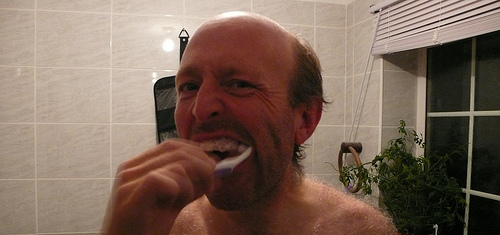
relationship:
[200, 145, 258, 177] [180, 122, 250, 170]
toothbrush in mouth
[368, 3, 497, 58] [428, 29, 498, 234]
mini-blinds on window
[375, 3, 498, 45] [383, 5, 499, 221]
mini-blinds on window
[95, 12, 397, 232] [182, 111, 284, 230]
man has mouth with toothbrush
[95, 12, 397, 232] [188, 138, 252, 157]
man top teeth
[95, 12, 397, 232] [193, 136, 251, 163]
man brushing teeth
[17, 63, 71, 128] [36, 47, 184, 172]
grout between tile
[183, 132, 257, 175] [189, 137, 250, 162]
mouth full of toothpaste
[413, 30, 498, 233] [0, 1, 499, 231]
window in bathroom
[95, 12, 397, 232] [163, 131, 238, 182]
man has hand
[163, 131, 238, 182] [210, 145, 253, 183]
hand holding toothbrush